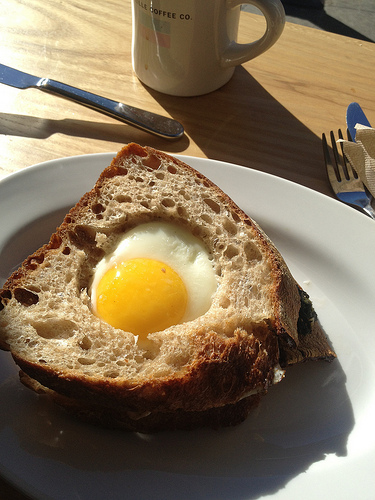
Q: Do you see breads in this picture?
A: Yes, there is a bread.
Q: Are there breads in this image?
A: Yes, there is a bread.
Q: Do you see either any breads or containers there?
A: Yes, there is a bread.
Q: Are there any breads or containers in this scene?
A: Yes, there is a bread.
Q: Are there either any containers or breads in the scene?
A: Yes, there is a bread.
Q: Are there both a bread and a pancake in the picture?
A: No, there is a bread but no pancakes.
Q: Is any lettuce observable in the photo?
A: No, there is no lettuce.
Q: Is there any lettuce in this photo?
A: No, there is no lettuce.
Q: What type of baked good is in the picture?
A: The baked good is a bread.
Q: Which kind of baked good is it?
A: The food is a bread.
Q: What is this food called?
A: This is a bread.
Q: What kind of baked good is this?
A: This is a bread.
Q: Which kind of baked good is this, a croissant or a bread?
A: This is a bread.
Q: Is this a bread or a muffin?
A: This is a bread.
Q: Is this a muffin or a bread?
A: This is a bread.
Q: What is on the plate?
A: The bread is on the plate.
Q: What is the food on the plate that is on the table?
A: The food is a bread.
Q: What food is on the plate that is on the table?
A: The food is a bread.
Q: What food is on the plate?
A: The food is a bread.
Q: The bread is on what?
A: The bread is on the plate.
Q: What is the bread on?
A: The bread is on the plate.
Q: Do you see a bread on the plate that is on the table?
A: Yes, there is a bread on the plate.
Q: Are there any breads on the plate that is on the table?
A: Yes, there is a bread on the plate.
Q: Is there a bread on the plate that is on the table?
A: Yes, there is a bread on the plate.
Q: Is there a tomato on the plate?
A: No, there is a bread on the plate.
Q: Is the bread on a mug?
A: No, the bread is on a plate.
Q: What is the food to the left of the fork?
A: The food is a bread.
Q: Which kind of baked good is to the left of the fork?
A: The food is a bread.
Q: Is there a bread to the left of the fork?
A: Yes, there is a bread to the left of the fork.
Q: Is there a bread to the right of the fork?
A: No, the bread is to the left of the fork.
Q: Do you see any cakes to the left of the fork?
A: No, there is a bread to the left of the fork.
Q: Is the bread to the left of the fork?
A: Yes, the bread is to the left of the fork.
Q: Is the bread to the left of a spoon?
A: No, the bread is to the left of the fork.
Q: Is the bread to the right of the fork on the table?
A: No, the bread is to the left of the fork.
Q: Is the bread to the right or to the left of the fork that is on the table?
A: The bread is to the left of the fork.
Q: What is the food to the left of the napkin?
A: The food is a bread.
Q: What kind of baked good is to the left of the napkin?
A: The food is a bread.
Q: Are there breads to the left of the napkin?
A: Yes, there is a bread to the left of the napkin.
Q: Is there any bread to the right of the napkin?
A: No, the bread is to the left of the napkin.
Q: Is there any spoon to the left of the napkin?
A: No, there is a bread to the left of the napkin.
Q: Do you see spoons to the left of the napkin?
A: No, there is a bread to the left of the napkin.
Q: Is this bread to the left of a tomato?
A: No, the bread is to the left of the napkin.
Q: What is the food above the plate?
A: The food is a bread.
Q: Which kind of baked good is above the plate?
A: The food is a bread.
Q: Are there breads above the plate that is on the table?
A: Yes, there is a bread above the plate.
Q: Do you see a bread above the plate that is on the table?
A: Yes, there is a bread above the plate.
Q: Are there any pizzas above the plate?
A: No, there is a bread above the plate.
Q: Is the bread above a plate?
A: Yes, the bread is above a plate.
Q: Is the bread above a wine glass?
A: No, the bread is above a plate.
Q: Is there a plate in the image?
A: Yes, there is a plate.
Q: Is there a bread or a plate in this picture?
A: Yes, there is a plate.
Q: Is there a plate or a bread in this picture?
A: Yes, there is a plate.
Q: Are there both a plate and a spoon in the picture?
A: No, there is a plate but no spoons.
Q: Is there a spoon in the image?
A: No, there are no spoons.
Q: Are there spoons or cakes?
A: No, there are no spoons or cakes.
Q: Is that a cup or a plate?
A: That is a plate.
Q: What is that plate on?
A: The plate is on the table.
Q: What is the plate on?
A: The plate is on the table.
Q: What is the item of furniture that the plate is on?
A: The piece of furniture is a table.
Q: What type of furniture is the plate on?
A: The plate is on the table.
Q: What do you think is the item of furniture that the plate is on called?
A: The piece of furniture is a table.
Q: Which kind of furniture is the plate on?
A: The plate is on the table.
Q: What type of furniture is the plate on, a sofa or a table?
A: The plate is on a table.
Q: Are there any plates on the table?
A: Yes, there is a plate on the table.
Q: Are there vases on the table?
A: No, there is a plate on the table.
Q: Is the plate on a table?
A: Yes, the plate is on a table.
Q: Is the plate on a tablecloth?
A: No, the plate is on a table.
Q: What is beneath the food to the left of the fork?
A: The plate is beneath the bread.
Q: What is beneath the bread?
A: The plate is beneath the bread.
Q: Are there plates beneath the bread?
A: Yes, there is a plate beneath the bread.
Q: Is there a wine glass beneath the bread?
A: No, there is a plate beneath the bread.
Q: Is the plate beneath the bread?
A: Yes, the plate is beneath the bread.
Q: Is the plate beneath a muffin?
A: No, the plate is beneath the bread.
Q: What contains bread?
A: The plate contains bread.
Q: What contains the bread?
A: The plate contains bread.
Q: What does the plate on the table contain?
A: The plate contains bread.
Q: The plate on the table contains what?
A: The plate contains bread.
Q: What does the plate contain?
A: The plate contains bread.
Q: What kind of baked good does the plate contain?
A: The plate contains bread.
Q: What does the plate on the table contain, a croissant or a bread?
A: The plate contains a bread.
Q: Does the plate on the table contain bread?
A: Yes, the plate contains bread.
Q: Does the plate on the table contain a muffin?
A: No, the plate contains bread.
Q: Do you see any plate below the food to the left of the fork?
A: Yes, there is a plate below the bread.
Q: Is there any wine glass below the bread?
A: No, there is a plate below the bread.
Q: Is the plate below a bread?
A: Yes, the plate is below a bread.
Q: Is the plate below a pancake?
A: No, the plate is below a bread.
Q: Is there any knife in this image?
A: Yes, there is a knife.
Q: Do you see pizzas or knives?
A: Yes, there is a knife.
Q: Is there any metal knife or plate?
A: Yes, there is a metal knife.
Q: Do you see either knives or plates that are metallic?
A: Yes, the knife is metallic.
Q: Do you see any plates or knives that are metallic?
A: Yes, the knife is metallic.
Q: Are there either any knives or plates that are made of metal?
A: Yes, the knife is made of metal.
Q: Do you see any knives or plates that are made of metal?
A: Yes, the knife is made of metal.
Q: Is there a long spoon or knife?
A: Yes, there is a long knife.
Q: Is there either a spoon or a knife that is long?
A: Yes, the knife is long.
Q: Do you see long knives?
A: Yes, there is a long knife.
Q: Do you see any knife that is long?
A: Yes, there is a knife that is long.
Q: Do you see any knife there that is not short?
A: Yes, there is a long knife.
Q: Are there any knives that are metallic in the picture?
A: Yes, there is a metal knife.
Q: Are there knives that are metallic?
A: Yes, there is a knife that is metallic.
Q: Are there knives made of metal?
A: Yes, there is a knife that is made of metal.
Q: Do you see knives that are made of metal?
A: Yes, there is a knife that is made of metal.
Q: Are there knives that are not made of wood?
A: Yes, there is a knife that is made of metal.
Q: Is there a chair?
A: No, there are no chairs.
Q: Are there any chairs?
A: No, there are no chairs.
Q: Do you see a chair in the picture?
A: No, there are no chairs.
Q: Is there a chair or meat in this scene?
A: No, there are no chairs or meat.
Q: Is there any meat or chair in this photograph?
A: No, there are no chairs or meat.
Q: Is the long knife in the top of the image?
A: Yes, the knife is in the top of the image.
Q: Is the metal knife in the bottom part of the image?
A: No, the knife is in the top of the image.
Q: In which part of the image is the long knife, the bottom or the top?
A: The knife is in the top of the image.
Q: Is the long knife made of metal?
A: Yes, the knife is made of metal.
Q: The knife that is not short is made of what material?
A: The knife is made of metal.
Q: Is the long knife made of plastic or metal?
A: The knife is made of metal.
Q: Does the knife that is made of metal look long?
A: Yes, the knife is long.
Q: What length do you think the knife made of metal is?
A: The knife is long.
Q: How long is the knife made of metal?
A: The knife is long.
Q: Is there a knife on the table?
A: Yes, there is a knife on the table.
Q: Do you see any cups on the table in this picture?
A: No, there is a knife on the table.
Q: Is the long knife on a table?
A: Yes, the knife is on a table.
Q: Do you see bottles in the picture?
A: No, there are no bottles.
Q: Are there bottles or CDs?
A: No, there are no bottles or cds.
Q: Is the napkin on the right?
A: Yes, the napkin is on the right of the image.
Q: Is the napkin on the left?
A: No, the napkin is on the right of the image.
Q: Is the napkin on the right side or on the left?
A: The napkin is on the right of the image.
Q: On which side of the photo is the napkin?
A: The napkin is on the right of the image.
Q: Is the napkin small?
A: Yes, the napkin is small.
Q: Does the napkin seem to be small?
A: Yes, the napkin is small.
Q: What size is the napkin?
A: The napkin is small.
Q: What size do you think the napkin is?
A: The napkin is small.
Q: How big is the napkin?
A: The napkin is small.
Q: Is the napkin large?
A: No, the napkin is small.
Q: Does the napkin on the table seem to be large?
A: No, the napkin is small.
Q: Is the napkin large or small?
A: The napkin is small.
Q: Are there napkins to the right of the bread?
A: Yes, there is a napkin to the right of the bread.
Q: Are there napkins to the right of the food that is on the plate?
A: Yes, there is a napkin to the right of the bread.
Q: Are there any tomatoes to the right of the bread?
A: No, there is a napkin to the right of the bread.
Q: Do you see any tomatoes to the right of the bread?
A: No, there is a napkin to the right of the bread.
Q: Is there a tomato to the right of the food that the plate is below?
A: No, there is a napkin to the right of the bread.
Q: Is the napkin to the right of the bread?
A: Yes, the napkin is to the right of the bread.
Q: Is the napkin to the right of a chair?
A: No, the napkin is to the right of the bread.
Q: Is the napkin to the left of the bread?
A: No, the napkin is to the right of the bread.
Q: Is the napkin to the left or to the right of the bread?
A: The napkin is to the right of the bread.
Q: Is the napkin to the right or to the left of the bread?
A: The napkin is to the right of the bread.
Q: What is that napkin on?
A: The napkin is on the table.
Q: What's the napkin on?
A: The napkin is on the table.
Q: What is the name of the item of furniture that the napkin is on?
A: The piece of furniture is a table.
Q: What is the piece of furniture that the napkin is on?
A: The piece of furniture is a table.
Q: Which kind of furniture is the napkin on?
A: The napkin is on the table.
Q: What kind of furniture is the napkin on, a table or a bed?
A: The napkin is on a table.